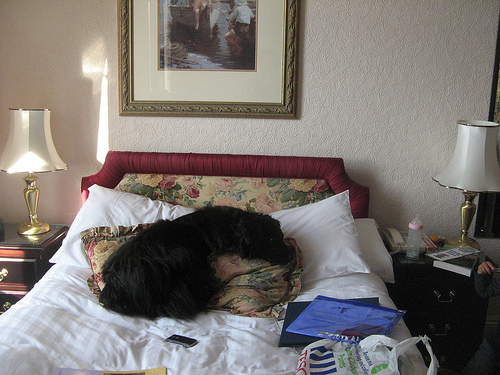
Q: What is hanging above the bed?
A: A picture.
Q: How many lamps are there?
A: Two.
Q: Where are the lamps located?
A: End tables.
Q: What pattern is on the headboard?
A: Flowers.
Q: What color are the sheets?
A: White.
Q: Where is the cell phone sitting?
A: On the bed.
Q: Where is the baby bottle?
A: The right end table.